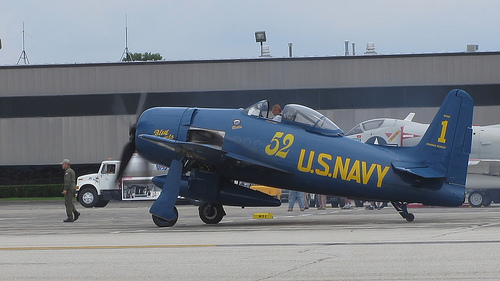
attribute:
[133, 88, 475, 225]
plane — riding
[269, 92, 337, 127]
glass — open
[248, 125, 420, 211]
writing — yellow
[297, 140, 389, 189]
signage — yellow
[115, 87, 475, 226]
aircraft — white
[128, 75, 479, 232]
airplane — US Navy, blue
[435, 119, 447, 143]
writing — yellow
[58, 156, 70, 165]
cap — green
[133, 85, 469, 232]
blue plane — navy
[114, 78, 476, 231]
plane — blue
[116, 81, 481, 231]
plain — taking off, getting ready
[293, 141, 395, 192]
letters — yellow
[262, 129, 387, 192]
writing — yellow